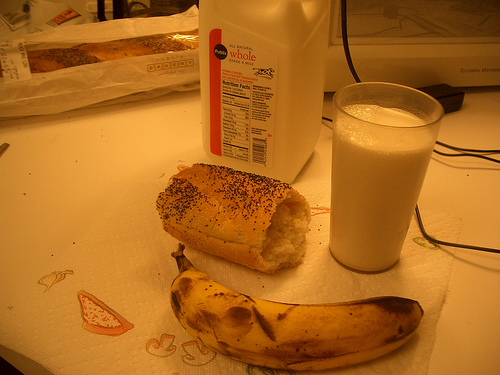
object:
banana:
[168, 242, 424, 371]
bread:
[21, 30, 202, 75]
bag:
[0, 4, 200, 120]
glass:
[328, 80, 445, 273]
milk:
[328, 104, 435, 272]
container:
[196, 0, 329, 185]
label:
[206, 27, 276, 166]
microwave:
[324, 0, 500, 91]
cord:
[339, 1, 361, 84]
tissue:
[1, 168, 463, 375]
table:
[1, 83, 500, 375]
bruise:
[250, 303, 277, 342]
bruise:
[224, 306, 253, 337]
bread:
[155, 159, 311, 276]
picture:
[75, 288, 134, 337]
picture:
[145, 332, 176, 359]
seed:
[204, 224, 208, 228]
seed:
[214, 218, 219, 222]